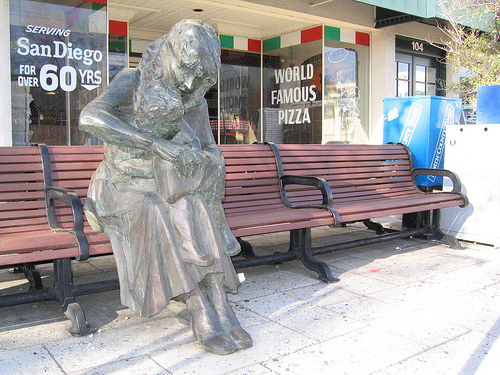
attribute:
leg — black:
[53, 260, 92, 334]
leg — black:
[291, 229, 336, 284]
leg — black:
[428, 211, 462, 248]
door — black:
[327, 40, 408, 101]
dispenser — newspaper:
[371, 99, 496, 206]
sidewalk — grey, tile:
[1, 213, 498, 373]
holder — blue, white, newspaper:
[382, 95, 462, 186]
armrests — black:
[409, 164, 464, 195]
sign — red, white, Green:
[107, 15, 373, 49]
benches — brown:
[2, 145, 452, 256]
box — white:
[429, 121, 498, 238]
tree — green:
[424, 0, 492, 122]